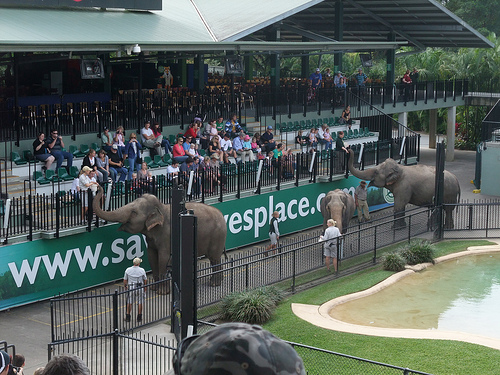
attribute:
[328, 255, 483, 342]
water — shallow